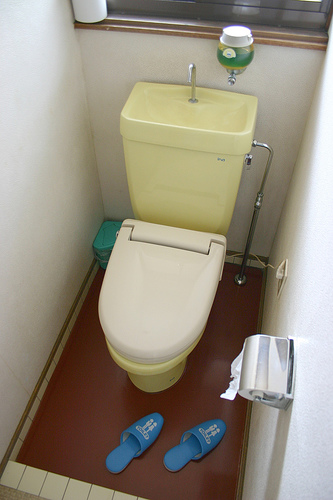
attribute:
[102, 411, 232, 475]
slippers — white, blue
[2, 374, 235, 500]
floor — brown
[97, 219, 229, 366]
seat — white, closed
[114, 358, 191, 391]
basin — yellow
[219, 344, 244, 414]
paper — white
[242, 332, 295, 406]
holder — silver, mounted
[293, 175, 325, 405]
wall — white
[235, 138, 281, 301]
pipe — silver, metal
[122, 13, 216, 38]
windowsill — wooden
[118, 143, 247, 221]
watertank — beige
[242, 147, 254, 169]
handle — silver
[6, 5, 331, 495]
bathroom — small